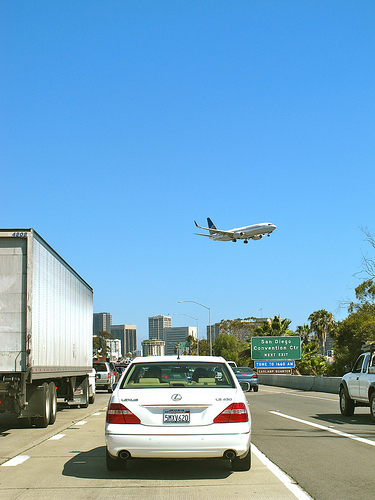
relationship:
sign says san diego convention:
[249, 333, 302, 362] [253, 338, 302, 353]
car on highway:
[102, 354, 251, 477] [4, 377, 374, 499]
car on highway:
[228, 365, 262, 392] [4, 377, 374, 499]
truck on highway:
[336, 347, 374, 425] [4, 377, 374, 499]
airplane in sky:
[192, 215, 278, 245] [1, 1, 373, 356]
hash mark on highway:
[2, 451, 34, 469] [4, 377, 374, 499]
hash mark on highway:
[47, 427, 68, 443] [4, 377, 374, 499]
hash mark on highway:
[75, 417, 89, 429] [4, 377, 374, 499]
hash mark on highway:
[90, 410, 105, 419] [4, 377, 374, 499]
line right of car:
[268, 408, 373, 452] [102, 354, 251, 477]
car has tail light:
[102, 354, 251, 477] [212, 403, 248, 424]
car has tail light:
[102, 354, 251, 477] [105, 400, 143, 427]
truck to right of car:
[336, 347, 374, 425] [102, 354, 251, 477]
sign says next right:
[249, 333, 302, 362] [262, 350, 291, 358]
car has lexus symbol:
[102, 354, 251, 477] [169, 391, 186, 403]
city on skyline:
[95, 311, 285, 372] [93, 305, 374, 366]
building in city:
[163, 325, 197, 354] [95, 311, 285, 372]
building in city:
[148, 314, 171, 341] [95, 311, 285, 372]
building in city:
[141, 338, 167, 356] [95, 311, 285, 372]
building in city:
[108, 323, 139, 357] [95, 311, 285, 372]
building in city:
[94, 309, 114, 338] [95, 311, 285, 372]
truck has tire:
[2, 227, 97, 432] [27, 380, 51, 429]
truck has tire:
[2, 227, 97, 432] [48, 381, 59, 426]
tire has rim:
[27, 380, 51, 429] [44, 390, 51, 422]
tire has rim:
[48, 381, 59, 426] [52, 395, 57, 418]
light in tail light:
[106, 408, 136, 416] [105, 400, 143, 427]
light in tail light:
[221, 409, 249, 416] [212, 403, 248, 424]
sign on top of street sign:
[249, 333, 302, 362] [252, 358, 298, 371]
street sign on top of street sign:
[252, 358, 298, 371] [257, 365, 294, 377]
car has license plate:
[102, 354, 251, 477] [161, 410, 191, 426]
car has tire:
[102, 354, 251, 477] [104, 446, 129, 473]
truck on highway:
[2, 227, 97, 432] [4, 377, 374, 499]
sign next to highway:
[249, 333, 302, 362] [4, 377, 374, 499]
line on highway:
[268, 408, 373, 452] [4, 377, 374, 499]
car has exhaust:
[102, 354, 251, 477] [115, 447, 131, 463]